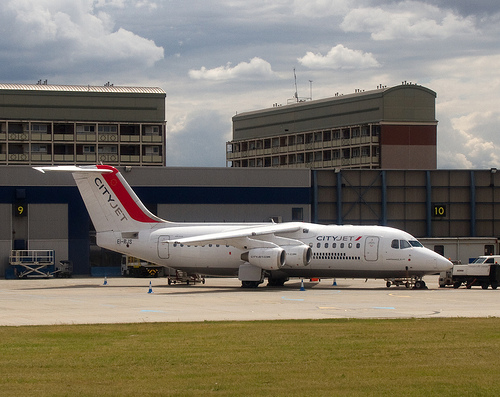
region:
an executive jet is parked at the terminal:
[31, 162, 453, 290]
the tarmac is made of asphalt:
[1, 278, 499, 323]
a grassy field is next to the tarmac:
[1, 314, 499, 395]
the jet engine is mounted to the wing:
[231, 237, 285, 271]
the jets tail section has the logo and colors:
[32, 163, 172, 264]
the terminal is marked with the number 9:
[11, 201, 26, 216]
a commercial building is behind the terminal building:
[226, 78, 438, 168]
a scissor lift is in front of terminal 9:
[7, 248, 57, 279]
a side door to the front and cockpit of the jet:
[362, 234, 380, 262]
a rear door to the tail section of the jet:
[156, 233, 171, 259]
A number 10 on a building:
[427, 196, 449, 222]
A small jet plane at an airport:
[43, 157, 477, 301]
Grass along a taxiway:
[119, 319, 391, 377]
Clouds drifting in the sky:
[305, 13, 450, 73]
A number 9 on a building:
[5, 190, 37, 221]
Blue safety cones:
[92, 265, 157, 291]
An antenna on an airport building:
[281, 62, 312, 109]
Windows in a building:
[92, 112, 172, 178]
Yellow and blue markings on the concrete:
[358, 287, 418, 314]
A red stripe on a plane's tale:
[80, 152, 178, 231]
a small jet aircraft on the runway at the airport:
[26, 147, 464, 306]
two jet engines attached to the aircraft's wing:
[241, 233, 316, 278]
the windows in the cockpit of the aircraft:
[387, 239, 426, 253]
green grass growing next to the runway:
[1, 329, 498, 392]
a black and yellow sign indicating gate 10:
[430, 201, 450, 217]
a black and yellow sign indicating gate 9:
[10, 201, 28, 220]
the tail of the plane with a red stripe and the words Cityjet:
[25, 161, 162, 231]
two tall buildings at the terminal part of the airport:
[7, 58, 448, 175]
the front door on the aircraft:
[366, 232, 381, 265]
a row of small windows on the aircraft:
[316, 242, 366, 255]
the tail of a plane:
[23, 150, 170, 270]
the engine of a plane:
[239, 245, 291, 273]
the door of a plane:
[359, 231, 384, 264]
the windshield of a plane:
[385, 234, 428, 251]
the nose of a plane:
[419, 247, 461, 277]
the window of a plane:
[353, 239, 363, 252]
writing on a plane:
[311, 229, 358, 244]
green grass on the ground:
[0, 310, 499, 395]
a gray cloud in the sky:
[182, 50, 294, 92]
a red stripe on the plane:
[93, 162, 165, 227]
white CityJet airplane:
[31, 162, 456, 273]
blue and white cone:
[146, 278, 153, 291]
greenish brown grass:
[8, 331, 488, 392]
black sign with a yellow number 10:
[433, 207, 444, 215]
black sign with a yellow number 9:
[16, 205, 24, 214]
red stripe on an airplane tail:
[93, 165, 132, 222]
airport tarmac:
[4, 292, 494, 314]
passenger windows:
[314, 240, 360, 252]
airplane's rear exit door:
[158, 233, 169, 257]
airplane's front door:
[366, 235, 380, 259]